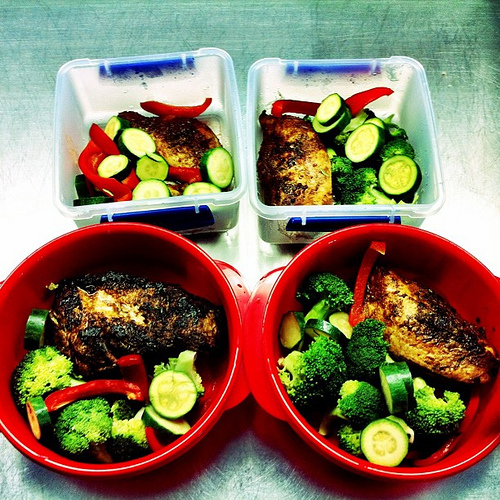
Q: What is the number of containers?
A: 4.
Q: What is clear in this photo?
A: Containers.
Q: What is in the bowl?
A: Food.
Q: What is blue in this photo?
A: Handles.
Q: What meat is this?
A: Chicken.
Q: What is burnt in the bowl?
A: Part of the chicken.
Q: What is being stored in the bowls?
A: Meals.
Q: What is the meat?
A: Chicken.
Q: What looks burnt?
A: The chicken.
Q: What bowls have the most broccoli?
A: The red bowls.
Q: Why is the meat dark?
A: Grilled.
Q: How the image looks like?
A: Yummy.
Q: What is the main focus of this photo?
A: Food in containers.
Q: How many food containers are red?
A: Two.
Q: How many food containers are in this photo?
A: Four.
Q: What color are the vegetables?
A: Green and red.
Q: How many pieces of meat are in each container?
A: One.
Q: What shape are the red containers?
A: Circular.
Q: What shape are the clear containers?
A: Square.